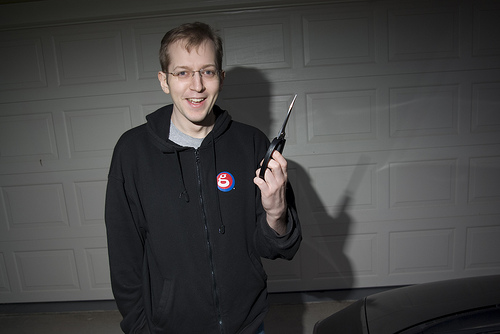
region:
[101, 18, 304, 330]
A man holding a pair of scissors.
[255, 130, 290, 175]
The scissors have a black handle.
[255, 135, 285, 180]
The man's finger are in the scissor handles.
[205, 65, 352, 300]
The man's shadow is on the garage door.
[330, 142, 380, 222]
A shadow of the scissors is on the garage door.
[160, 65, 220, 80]
The man is wearing glasses.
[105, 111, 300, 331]
The man is wearing a dark jacket.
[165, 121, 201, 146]
The man is wearing a gray shirt underneath the jacket.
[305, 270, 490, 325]
The front edge of a vehicle.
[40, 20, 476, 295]
A white garage door.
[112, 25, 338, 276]
a man holding a pair of scissors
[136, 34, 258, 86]
a man wearing glasses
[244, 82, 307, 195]
a pair of scissors with black handles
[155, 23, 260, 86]
a man with blonde hair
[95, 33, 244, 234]
a man wearing a black jacket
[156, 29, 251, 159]
a man wearing a grey shirt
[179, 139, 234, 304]
a black jacket with a black zipper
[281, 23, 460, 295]
a white garage door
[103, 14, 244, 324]
a man with his hand in his pocket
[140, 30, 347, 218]
a man holding up a pair of scissors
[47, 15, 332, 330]
Man holding sizzors in hand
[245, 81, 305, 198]
Pair of black handled sissors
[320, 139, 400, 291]
Shadow cast by the sissors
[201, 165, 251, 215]
Red white and blue logo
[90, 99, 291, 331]
Black hooded jacket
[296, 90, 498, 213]
White panels on the door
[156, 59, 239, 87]
Silver rimmed glasses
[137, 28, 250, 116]
Man wearing glasses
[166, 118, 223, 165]
Man wearing grey undershirt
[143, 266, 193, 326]
pocket in jacket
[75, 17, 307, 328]
a man holding scissors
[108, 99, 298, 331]
A black hooded sweatshirt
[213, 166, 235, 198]
A red and blue logo on a sweatshirt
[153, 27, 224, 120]
A man wearing glasses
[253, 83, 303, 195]
A pair of black scissors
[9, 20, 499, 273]
A white garage door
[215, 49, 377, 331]
A shadow of a man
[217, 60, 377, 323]
A shadow of a man holding scissors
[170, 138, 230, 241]
Two strings on a jacket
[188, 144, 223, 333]
A zipper on a jacket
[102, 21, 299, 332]
A man holding a pair of scissors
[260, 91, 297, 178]
A pair of scissors with black handles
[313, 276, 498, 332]
The corner edge of a black car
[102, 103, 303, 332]
A black hoodie on a man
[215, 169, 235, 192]
A red, white and blue logo on a hoodie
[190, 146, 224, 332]
A zipper on a black hoodie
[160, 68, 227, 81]
A pair of thin framed glasses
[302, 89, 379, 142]
A garage door panel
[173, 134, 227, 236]
The drawstrings on a black hoodie